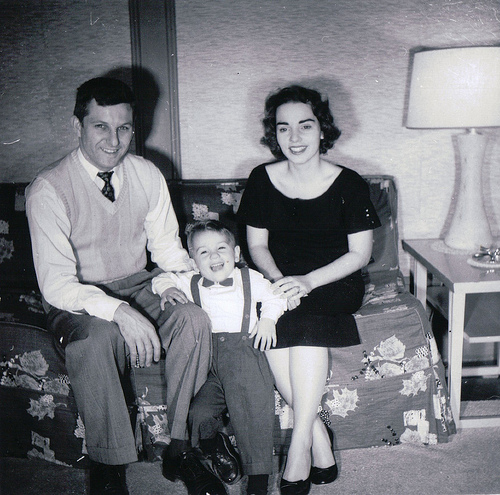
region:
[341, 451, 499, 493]
carpeted floor for comfort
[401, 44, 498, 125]
white lamp shade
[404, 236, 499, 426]
end table for sitting items on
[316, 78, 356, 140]
shadow of woman's head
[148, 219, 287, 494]
young caucasian male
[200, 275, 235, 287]
bow tie for style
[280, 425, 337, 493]
black shoes for feet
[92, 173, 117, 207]
tie for style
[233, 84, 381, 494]
older woman who appears to be a mother to the younger male and a wife to the older male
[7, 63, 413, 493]
A family sitting on the couch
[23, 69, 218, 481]
a man wearing a tie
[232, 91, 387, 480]
a woman wearing a dress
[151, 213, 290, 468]
a little boy wearing a bowtie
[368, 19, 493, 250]
a lamp on the table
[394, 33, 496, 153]
a lamp shade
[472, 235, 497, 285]
an ashtray on the table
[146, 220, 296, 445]
a boy wearing suspenders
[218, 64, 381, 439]
a woman with short brown hair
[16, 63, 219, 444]
a man wearing a white dress shirt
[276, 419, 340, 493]
A pair of black high heels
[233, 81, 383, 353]
A woman is wearing a black dress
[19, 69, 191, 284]
A man is wearing a vest and tie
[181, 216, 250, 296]
Boy is wearing a bowtie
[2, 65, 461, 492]
A man, boy and woman are sitting on a couch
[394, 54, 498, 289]
A lamp on an end table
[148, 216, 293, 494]
A young boy is wearing suspenders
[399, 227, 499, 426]
An end table next to a couch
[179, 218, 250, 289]
A boy is smiling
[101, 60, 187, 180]
Man's shadow on the wall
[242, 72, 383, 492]
woman with dark brown hair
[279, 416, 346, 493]
Black shoes on woman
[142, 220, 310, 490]
Little boy smiling in between man and woman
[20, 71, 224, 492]
Man with dark hair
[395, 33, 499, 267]
White lamp with shade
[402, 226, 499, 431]
White table by the sofa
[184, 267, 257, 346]
Black suspenders on boys shirt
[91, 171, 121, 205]
Black tie on man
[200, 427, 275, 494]
Black shoes and socks on boy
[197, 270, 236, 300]
Black bowtie on boy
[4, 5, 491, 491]
The picture is in black and white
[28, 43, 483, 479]
This picture was taken many decades ago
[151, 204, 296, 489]
This is a small boy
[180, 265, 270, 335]
The boy is wearing suspenders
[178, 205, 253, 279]
The boy is smiling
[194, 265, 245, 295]
The boy is wearing a bow tie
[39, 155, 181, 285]
The man is wearing a sweater vest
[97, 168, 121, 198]
The man is wearing a neck tie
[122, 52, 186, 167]
Shadow of the man on the wall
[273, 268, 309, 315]
Woman's hand folded over one another